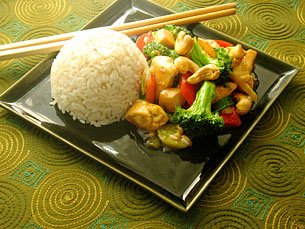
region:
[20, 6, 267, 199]
asian meal on a plate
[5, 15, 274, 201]
tasty asian meal on a plate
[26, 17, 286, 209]
delicious asian meal on a plate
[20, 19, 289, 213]
flavorful asian meal on a plate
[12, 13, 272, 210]
hot asian meal on a plate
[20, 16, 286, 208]
very nice asian meal on a plate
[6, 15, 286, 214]
great asian meal on a plate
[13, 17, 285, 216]
special asian meal on a plate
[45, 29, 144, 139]
ball of rice on a plate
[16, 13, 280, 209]
well cooked asian meal on a plate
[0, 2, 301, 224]
a plate of food on cloth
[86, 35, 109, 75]
white rice cooked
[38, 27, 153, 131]
a big ball of rice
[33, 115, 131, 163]
the shadow of the rice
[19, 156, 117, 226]
round shapes of gold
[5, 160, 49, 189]
little blue lines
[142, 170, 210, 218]
the bottom coner of plate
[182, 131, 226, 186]
the shadow of the borricol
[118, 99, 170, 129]
a cubed piece of cooked chicken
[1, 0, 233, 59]
two chop sticks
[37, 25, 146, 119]
white rice ina ball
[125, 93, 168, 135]
cooked chicken cubed style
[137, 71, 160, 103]
a sliced red pepper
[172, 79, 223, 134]
a piece of green broilli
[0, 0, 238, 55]
two wooden chop sticks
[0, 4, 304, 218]
a square plate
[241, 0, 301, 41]
a gold curile on cloth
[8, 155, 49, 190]
blue lines on table cloth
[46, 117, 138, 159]
a shadow of rice on plate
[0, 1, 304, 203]
a plate of food sits on a cloth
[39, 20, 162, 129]
a ball of white rice.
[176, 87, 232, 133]
a piece of green broccoli.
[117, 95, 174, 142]
a piece of cooked meat.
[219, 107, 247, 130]
sliced red pepper.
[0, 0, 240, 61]
chop sticks on a plate.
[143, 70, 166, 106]
a slice of orange carrot.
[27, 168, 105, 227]
a circular shape on a table.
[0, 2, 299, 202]
a square black plate.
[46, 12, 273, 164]
chinese food on top of a plate.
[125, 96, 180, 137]
fried meat.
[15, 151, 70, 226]
this is a table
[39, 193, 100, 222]
the cloth is green in color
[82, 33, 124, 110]
this is the rice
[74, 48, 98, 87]
the rice is white in color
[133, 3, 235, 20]
these are chopsticks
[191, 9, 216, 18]
the chopsticks are brown in color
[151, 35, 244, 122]
this is some food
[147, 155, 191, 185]
this is a tray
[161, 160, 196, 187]
the tray is black in color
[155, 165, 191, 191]
the tray is metallic